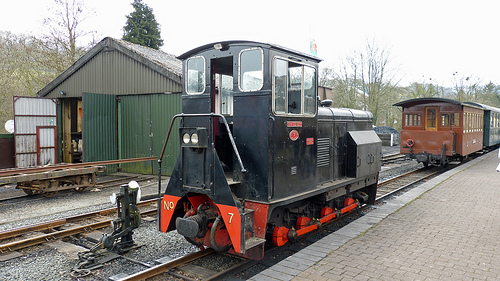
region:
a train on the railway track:
[161, 28, 381, 260]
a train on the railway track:
[394, 81, 499, 168]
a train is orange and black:
[151, 40, 385, 253]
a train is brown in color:
[393, 97, 499, 163]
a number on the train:
[213, 200, 250, 256]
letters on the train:
[161, 195, 178, 213]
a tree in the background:
[118, 0, 165, 46]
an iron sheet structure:
[13, 33, 184, 173]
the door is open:
[9, 97, 82, 162]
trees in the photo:
[1, 32, 493, 146]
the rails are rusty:
[9, 142, 281, 274]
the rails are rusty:
[7, 176, 172, 272]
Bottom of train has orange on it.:
[148, 187, 255, 277]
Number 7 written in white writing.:
[166, 180, 265, 250]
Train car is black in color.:
[178, 62, 321, 184]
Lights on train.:
[147, 112, 222, 165]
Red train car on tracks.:
[368, 95, 495, 245]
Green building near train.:
[12, 71, 213, 200]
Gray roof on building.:
[86, 30, 177, 105]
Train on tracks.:
[116, 127, 252, 259]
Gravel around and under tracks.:
[51, 209, 194, 269]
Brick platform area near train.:
[296, 230, 497, 263]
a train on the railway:
[158, 39, 386, 256]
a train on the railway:
[384, 91, 498, 167]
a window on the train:
[181, 50, 210, 96]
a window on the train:
[233, 46, 266, 93]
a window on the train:
[272, 62, 316, 118]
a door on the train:
[211, 52, 242, 179]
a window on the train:
[425, 108, 438, 131]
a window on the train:
[471, 110, 475, 131]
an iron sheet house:
[15, 34, 185, 168]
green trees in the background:
[332, 58, 499, 146]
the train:
[124, 50, 344, 275]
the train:
[139, 36, 251, 271]